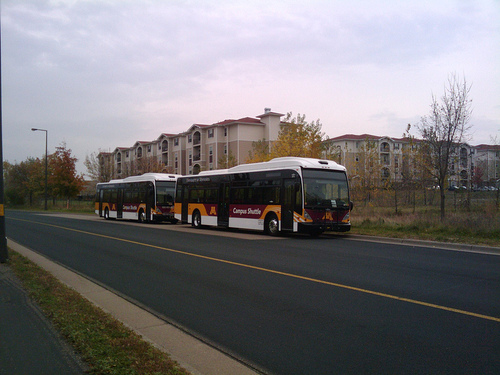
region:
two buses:
[91, 148, 356, 250]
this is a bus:
[170, 143, 354, 251]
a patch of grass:
[1, 243, 198, 373]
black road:
[1, 204, 499, 373]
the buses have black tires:
[185, 207, 279, 240]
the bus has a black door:
[271, 176, 301, 236]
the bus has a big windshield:
[298, 166, 356, 211]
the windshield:
[298, 162, 353, 222]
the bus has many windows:
[168, 177, 293, 208]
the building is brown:
[79, 99, 498, 196]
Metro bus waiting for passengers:
[177, 153, 359, 240]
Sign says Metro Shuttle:
[229, 202, 263, 226]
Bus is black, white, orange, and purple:
[92, 177, 168, 220]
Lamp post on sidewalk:
[26, 122, 54, 222]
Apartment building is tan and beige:
[108, 136, 235, 169]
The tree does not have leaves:
[417, 90, 472, 230]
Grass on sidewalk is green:
[31, 265, 118, 356]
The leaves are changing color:
[48, 143, 86, 203]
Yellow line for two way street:
[296, 247, 451, 325]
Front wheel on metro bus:
[257, 205, 287, 243]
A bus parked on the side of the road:
[174, 155, 355, 240]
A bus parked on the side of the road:
[93, 172, 173, 225]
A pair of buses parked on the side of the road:
[89, 149, 351, 242]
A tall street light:
[26, 123, 61, 214]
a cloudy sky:
[11, 0, 494, 139]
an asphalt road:
[8, 210, 498, 360]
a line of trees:
[0, 152, 76, 209]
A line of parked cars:
[421, 182, 498, 190]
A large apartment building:
[86, 105, 331, 188]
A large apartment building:
[313, 117, 473, 187]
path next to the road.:
[7, 312, 22, 367]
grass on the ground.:
[99, 336, 140, 369]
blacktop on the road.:
[235, 310, 346, 353]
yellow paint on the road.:
[323, 275, 397, 307]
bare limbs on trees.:
[443, 87, 473, 132]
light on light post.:
[27, 120, 51, 135]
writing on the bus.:
[226, 207, 259, 218]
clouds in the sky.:
[97, 82, 162, 114]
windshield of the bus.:
[311, 182, 341, 194]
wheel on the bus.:
[263, 215, 278, 235]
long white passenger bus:
[168, 152, 358, 238]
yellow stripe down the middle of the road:
[87, 224, 464, 331]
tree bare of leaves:
[399, 73, 475, 229]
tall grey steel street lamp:
[29, 124, 52, 212]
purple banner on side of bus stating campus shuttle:
[227, 202, 267, 217]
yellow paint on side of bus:
[184, 194, 216, 223]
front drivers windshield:
[297, 165, 349, 209]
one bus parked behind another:
[85, 169, 177, 228]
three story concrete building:
[321, 122, 474, 189]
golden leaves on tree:
[270, 115, 316, 158]